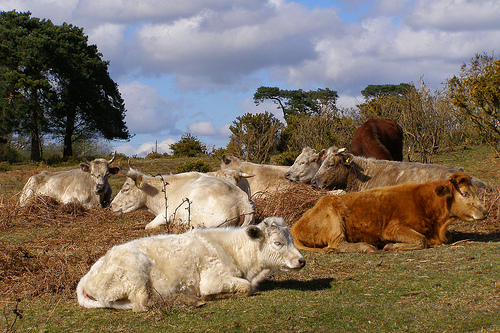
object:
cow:
[290, 171, 489, 254]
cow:
[311, 146, 487, 194]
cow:
[109, 159, 255, 230]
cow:
[19, 151, 119, 210]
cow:
[76, 216, 306, 312]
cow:
[284, 145, 316, 181]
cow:
[220, 153, 292, 203]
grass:
[294, 274, 498, 330]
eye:
[274, 242, 283, 247]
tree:
[0, 10, 131, 160]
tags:
[320, 154, 324, 158]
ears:
[341, 153, 355, 165]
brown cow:
[351, 117, 403, 161]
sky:
[240, 24, 334, 68]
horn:
[107, 150, 116, 164]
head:
[89, 158, 110, 195]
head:
[110, 169, 147, 215]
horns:
[77, 153, 89, 163]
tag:
[345, 158, 349, 163]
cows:
[205, 170, 256, 186]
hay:
[5, 239, 75, 300]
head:
[311, 153, 349, 190]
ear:
[244, 226, 265, 243]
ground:
[3, 291, 60, 331]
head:
[446, 170, 490, 222]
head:
[244, 217, 306, 273]